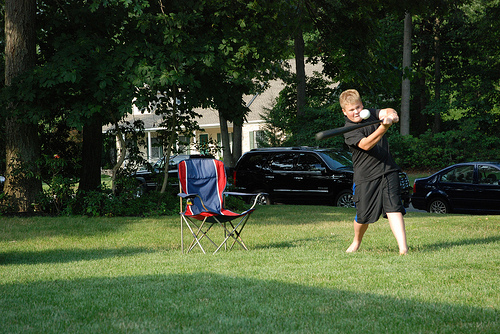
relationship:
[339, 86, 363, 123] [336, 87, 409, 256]
head of boy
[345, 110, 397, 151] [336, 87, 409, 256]
arm of boy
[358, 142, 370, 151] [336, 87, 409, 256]
elbow of boy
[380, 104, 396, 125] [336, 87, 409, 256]
hand of boy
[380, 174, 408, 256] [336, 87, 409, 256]
leg of boy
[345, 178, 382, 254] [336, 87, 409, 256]
leg of boy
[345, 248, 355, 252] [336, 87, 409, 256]
foot of boy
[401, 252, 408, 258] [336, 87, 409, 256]
foot of boy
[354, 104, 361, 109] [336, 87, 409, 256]
eye of boy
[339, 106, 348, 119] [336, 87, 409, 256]
ear of boy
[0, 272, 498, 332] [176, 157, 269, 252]
shadow next to chair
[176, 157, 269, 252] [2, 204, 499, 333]
chair on grass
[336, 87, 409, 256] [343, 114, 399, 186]
boy wearing black shirt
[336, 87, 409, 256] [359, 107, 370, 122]
boy hitting ball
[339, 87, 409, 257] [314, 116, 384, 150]
boy swinging bat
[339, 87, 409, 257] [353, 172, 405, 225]
boy wearing shorts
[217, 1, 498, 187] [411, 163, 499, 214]
trees behind car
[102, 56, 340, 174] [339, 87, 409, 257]
house behind boy